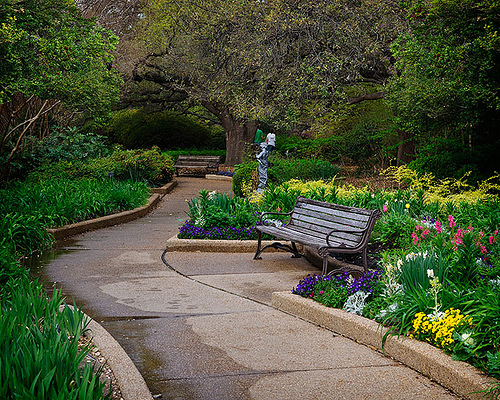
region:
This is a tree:
[187, 30, 272, 185]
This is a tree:
[247, 65, 264, 214]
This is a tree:
[129, 41, 221, 116]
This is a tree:
[197, 280, 295, 371]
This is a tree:
[267, 197, 334, 268]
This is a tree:
[400, 228, 432, 345]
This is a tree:
[343, 148, 479, 323]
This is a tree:
[37, 131, 139, 239]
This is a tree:
[108, 90, 228, 246]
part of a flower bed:
[338, 295, 355, 315]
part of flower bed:
[413, 280, 431, 292]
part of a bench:
[304, 207, 328, 234]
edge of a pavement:
[92, 213, 111, 233]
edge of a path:
[133, 321, 155, 336]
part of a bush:
[313, 160, 324, 179]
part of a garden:
[396, 264, 428, 291]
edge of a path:
[96, 345, 123, 359]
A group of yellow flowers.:
[408, 307, 472, 351]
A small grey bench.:
[252, 197, 389, 272]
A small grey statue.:
[248, 142, 279, 192]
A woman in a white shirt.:
[264, 122, 285, 151]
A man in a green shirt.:
[250, 114, 264, 156]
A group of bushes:
[15, 127, 114, 179]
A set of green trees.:
[0, 0, 112, 107]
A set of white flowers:
[342, 292, 369, 309]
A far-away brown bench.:
[167, 155, 221, 175]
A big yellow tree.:
[135, 0, 353, 132]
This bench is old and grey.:
[272, 198, 378, 279]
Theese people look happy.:
[203, 92, 328, 190]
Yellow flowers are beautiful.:
[396, 269, 478, 377]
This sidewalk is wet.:
[24, 146, 269, 396]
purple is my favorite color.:
[222, 188, 388, 331]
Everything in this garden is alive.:
[21, 19, 485, 378]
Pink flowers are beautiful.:
[391, 144, 485, 290]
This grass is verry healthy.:
[1, 219, 162, 379]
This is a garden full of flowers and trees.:
[11, 11, 479, 376]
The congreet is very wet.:
[1, 164, 362, 393]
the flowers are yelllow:
[402, 281, 482, 358]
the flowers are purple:
[291, 256, 323, 299]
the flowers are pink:
[402, 208, 490, 264]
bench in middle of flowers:
[227, 189, 389, 276]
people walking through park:
[242, 113, 301, 165]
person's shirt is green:
[240, 114, 262, 146]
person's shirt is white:
[257, 125, 282, 152]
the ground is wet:
[33, 216, 215, 392]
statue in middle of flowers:
[243, 130, 280, 204]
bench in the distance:
[160, 140, 241, 187]